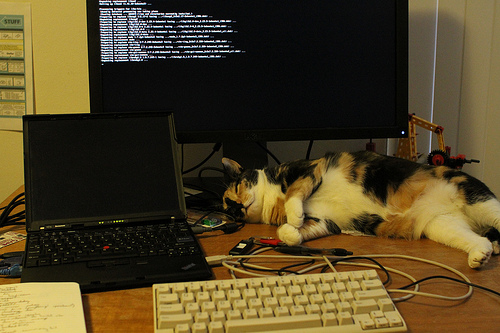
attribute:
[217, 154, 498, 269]
cat — sleeping, white, black &orange, brown, black, napping, relaxed, asleep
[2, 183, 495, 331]
desk — brown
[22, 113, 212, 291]
laptop computer — black, small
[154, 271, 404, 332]
computer keyboard — white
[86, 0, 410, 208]
computer monitor — black, big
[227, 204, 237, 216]
eye — black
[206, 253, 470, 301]
usb cable — white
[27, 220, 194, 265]
keyboard — black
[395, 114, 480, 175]
construction vehicle — a toy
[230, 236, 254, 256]
thumb drive — USB